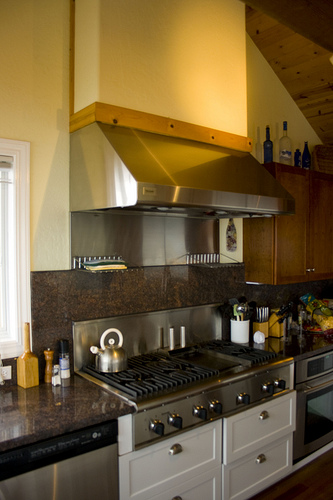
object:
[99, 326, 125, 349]
handle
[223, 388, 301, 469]
drawer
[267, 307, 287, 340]
nlock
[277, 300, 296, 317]
knieves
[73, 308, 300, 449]
cooktop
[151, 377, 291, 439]
control knobs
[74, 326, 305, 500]
stove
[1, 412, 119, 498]
dishwasher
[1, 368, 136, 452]
countertop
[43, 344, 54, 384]
grinder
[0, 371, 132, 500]
counter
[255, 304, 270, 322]
knife block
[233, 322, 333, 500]
counter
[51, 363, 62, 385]
salt shaker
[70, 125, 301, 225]
fan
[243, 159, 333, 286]
cabinet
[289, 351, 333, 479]
oven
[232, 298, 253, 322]
utensils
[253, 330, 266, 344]
timer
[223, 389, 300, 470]
drawers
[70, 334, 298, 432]
stove top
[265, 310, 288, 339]
holder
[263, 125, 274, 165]
bottle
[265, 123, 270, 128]
cork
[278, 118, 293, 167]
bottle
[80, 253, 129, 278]
holders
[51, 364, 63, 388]
salt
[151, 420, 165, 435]
knob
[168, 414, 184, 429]
knob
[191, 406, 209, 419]
knob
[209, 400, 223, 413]
knob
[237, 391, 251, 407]
knob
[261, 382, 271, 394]
knob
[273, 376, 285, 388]
knob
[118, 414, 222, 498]
drawer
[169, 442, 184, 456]
handle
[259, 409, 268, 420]
handle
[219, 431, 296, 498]
drawer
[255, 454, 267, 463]
handle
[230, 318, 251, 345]
bucket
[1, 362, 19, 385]
outlet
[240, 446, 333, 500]
ground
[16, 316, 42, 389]
object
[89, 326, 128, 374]
kettle